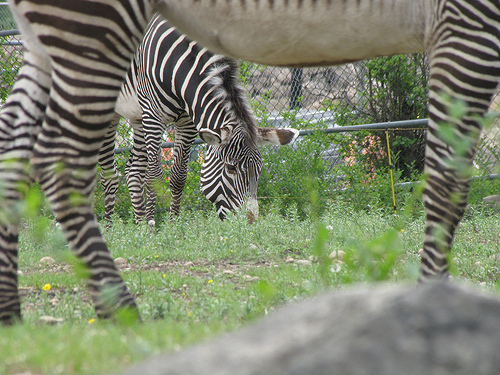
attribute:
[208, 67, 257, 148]
zebra mane — black, white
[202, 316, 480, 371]
boulder — large, in foreground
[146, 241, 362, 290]
patch — made of stone, made of soil